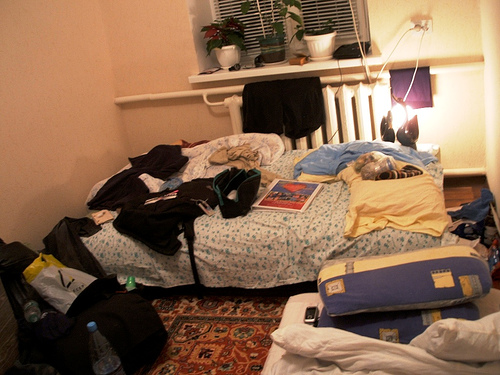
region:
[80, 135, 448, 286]
the bed is messy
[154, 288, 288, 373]
the carpet is multicolor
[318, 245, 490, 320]
the pillow is blue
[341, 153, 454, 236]
the pillowcase is yellow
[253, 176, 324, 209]
the magazine is on the bed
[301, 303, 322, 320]
the phone is on the chair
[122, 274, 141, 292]
the pop bottle is in the bag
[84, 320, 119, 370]
the water bottle is on the floor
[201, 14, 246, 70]
the plant is on the window sill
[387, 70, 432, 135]
the lamp is on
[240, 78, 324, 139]
pair of black shorts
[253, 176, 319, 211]
a magazine with a red heart on the cover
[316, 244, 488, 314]
yellow and blue pillow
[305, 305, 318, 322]
silver and black cell phone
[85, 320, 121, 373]
a water bottle with a blue cap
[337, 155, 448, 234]
a yellow pillow with socks on it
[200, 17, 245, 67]
a plant on a window sill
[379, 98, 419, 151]
a lamp with no lamp shade on it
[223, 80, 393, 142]
a white radiator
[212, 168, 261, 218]
a black bag with green trim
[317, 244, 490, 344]
Pillows on the bed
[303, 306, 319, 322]
A cell phone next to the pillows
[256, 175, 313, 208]
A book on the bed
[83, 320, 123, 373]
A plastic bottle by the bag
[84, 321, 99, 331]
The plastic bottle has a blue cap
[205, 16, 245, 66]
A potted plant by the window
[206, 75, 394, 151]
A radiator by the bed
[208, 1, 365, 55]
A window behind the potted plant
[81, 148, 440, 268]
A sheet on the bed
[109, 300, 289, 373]
A rug below the bed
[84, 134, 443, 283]
Messy bed with things on it.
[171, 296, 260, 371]
Carpet with oriental design.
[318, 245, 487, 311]
Pillow with blue and yellow patchwork pattern.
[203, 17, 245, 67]
Small indoor plant in a white pot.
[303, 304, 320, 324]
Black and silver cell phone.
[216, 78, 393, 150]
Radiator with shorts hanging on it.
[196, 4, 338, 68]
Three potted plants on a windowsill.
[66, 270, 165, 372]
Bag with plastic bottles in pockets.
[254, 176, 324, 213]
Magazine laying on a bed.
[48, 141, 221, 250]
Messy pile of clothing.